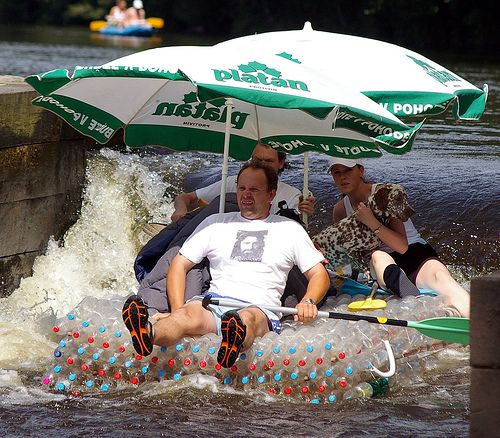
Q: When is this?
A: Daytime.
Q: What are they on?
A: Bottles.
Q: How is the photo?
A: Clear.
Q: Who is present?
A: People.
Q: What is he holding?
A: Paddle.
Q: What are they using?
A: Umbrellas.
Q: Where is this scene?
A: Water.